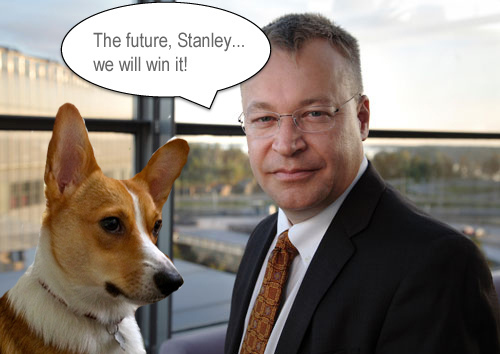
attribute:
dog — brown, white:
[10, 76, 172, 352]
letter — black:
[93, 31, 101, 46]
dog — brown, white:
[3, 99, 197, 352]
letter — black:
[138, 28, 153, 48]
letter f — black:
[121, 28, 130, 48]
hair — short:
[258, 9, 365, 100]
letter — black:
[149, 33, 161, 48]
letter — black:
[91, 26, 109, 51]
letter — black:
[161, 58, 169, 71]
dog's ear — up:
[37, 102, 103, 202]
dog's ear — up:
[127, 134, 197, 211]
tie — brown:
[246, 229, 308, 351]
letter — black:
[92, 30, 102, 49]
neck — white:
[30, 262, 124, 337]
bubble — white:
[53, 5, 293, 111]